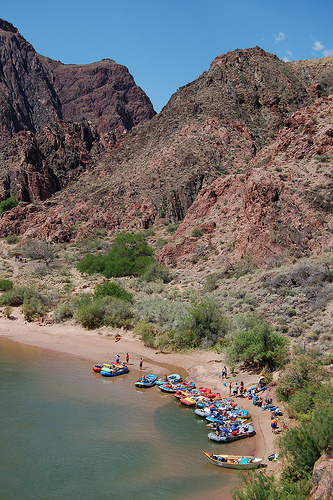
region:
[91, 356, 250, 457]
inflatable rafts parked near the shore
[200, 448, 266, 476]
small boat pushed up into sand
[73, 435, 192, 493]
shallow waters near the sandy shore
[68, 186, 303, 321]
plants growing on red rocky hills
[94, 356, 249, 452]
most of the rafts are blue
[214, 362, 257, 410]
people standing near supplies on shore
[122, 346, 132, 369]
person in red shirt and dark shorts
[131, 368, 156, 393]
blue and red inflatable raft on the water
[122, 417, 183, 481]
sand can be seen through shallow waters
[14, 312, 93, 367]
sand on the shores with water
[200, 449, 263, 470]
double ended river boat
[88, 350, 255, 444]
Colorful rafts beached on a riverbank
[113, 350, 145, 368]
three rafters onshore by colorful rafts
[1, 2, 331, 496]
colorful river rafts dot the beach below red red mountains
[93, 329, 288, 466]
group of rafters and their colorful rafts on the riverbank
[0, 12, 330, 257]
mountainess hills of red rock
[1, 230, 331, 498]
trees and sagebrush thrive near a riverbank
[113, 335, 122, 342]
red polystyrene kayak beached on a riverbank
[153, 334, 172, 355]
short tree growing on the riverbank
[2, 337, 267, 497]
shallow edge of river near bank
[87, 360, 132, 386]
the boats at the shore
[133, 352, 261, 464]
the boats at the shore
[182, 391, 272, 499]
the boats at the shore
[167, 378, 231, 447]
the boats at the shore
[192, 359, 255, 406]
the people at the shore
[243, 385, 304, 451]
the people at the shore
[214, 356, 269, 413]
the people at the shore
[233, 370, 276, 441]
the people at the shore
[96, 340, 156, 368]
the people at the shore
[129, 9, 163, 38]
this is the sky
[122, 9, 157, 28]
the sky is blue in color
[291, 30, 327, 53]
the sky has some clouds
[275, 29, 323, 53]
the clouds are white in color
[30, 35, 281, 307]
these are two hills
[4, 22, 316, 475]
the hills are big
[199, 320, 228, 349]
this is some grass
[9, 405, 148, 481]
this is the ocean water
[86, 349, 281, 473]
these are some boats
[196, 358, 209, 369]
the sand is brown in color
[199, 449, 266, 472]
This is a boat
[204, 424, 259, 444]
This is a boat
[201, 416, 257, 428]
This is a boat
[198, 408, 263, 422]
This is a boat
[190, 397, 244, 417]
This is a boat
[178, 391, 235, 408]
This is a boat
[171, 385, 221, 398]
This is a boat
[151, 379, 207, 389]
This is a boat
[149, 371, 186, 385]
This is a boat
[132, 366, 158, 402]
This is a boat